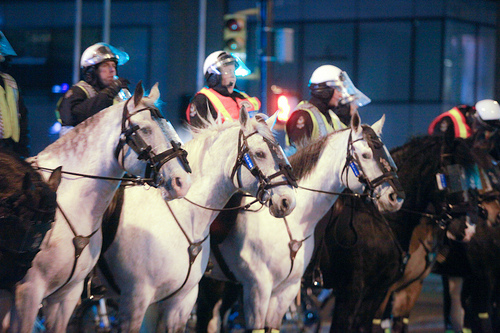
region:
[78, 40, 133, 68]
a white helmet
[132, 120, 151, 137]
the eye of a horse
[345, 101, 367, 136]
the ear of a horse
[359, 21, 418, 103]
a window of a building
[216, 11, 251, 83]
a yellow street light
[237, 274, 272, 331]
part of a horse leg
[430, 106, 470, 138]
part of a red and yellow safety jacket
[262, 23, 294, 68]
a small gray box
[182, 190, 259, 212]
a long brown rope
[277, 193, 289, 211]
the nose of a horse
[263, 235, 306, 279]
chest of a horse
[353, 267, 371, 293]
edge of a hip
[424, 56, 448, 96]
edge of a wall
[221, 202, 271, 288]
part of a horse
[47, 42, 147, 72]
Police officer Riot Helmet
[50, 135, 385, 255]
Three white horses with different manes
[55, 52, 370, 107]
Three Police Officers sitting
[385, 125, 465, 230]
One Black Horse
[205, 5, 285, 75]
Green Stop Light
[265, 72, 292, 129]
Red stop light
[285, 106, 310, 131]
One Police Officer Badge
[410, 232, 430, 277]
One Brown horse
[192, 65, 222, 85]
Police Officer Head set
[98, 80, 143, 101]
Police officer drinking from a Water bottle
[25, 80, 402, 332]
Three white horses in a row.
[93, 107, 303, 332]
White horse in the middle of two other white horses.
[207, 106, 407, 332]
White horse with dark brown mane.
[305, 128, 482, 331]
Dark brown horse to the right of three white horses.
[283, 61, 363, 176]
Officer on a dark brown horse to the right of three white horses.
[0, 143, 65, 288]
Brown horse to the left of a white horse.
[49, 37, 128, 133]
Officer on the middle white horse.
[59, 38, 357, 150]
Three officers on horses.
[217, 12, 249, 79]
Traffic light in the background with green illuminated.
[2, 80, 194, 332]
First white horse to the left of the other white horses.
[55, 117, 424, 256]
horses standing in a row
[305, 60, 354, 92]
white helmet on head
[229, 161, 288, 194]
bridle on horse face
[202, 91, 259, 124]
yellow and orange vest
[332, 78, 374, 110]
clear shield on helmet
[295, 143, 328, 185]
brown mane on white horse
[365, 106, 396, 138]
ear on horse head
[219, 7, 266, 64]
yellow traffic light on pole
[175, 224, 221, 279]
harness on horse chest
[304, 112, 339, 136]
yellow and silver vest